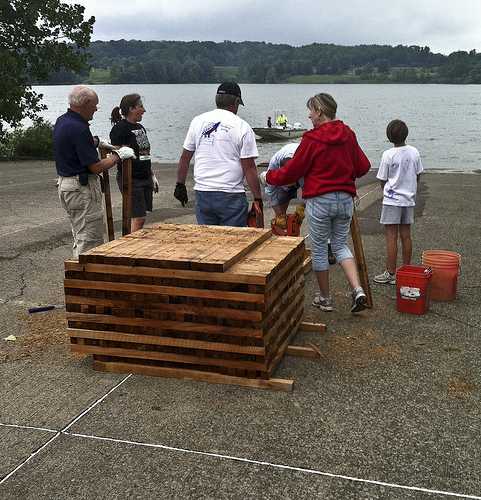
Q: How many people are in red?
A: One.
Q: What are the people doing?
A: Standing.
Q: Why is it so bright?
A: Sun light.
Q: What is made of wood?
A: The pallets.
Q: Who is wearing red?
A: The woman.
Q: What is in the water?
A: The boat.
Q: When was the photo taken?
A: Day time.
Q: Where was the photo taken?
A: Aside a lake.